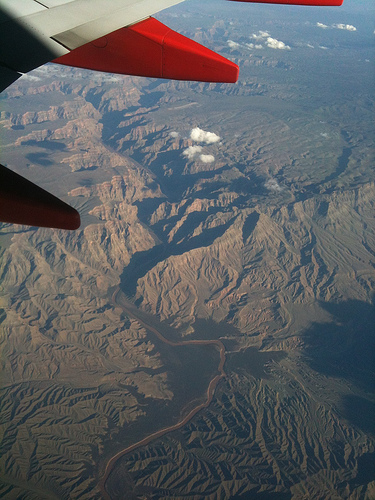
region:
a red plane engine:
[38, 15, 246, 84]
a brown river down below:
[87, 209, 235, 498]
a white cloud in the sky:
[160, 117, 229, 143]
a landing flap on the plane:
[50, 0, 185, 57]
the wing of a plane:
[1, 0, 202, 107]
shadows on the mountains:
[284, 288, 374, 451]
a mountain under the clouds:
[124, 176, 305, 324]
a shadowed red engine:
[0, 148, 101, 231]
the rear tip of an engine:
[225, 58, 245, 98]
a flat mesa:
[0, 86, 139, 260]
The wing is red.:
[33, 11, 246, 101]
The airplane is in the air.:
[1, 0, 276, 226]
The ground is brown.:
[31, 230, 347, 468]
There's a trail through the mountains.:
[73, 275, 239, 496]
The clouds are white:
[150, 108, 229, 172]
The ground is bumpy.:
[34, 107, 354, 270]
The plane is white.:
[1, 0, 211, 66]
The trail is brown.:
[99, 281, 246, 493]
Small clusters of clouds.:
[212, 9, 318, 64]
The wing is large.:
[1, 0, 284, 242]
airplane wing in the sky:
[0, 0, 358, 232]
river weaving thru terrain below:
[67, 88, 240, 497]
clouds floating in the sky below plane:
[167, 124, 224, 164]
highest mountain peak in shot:
[205, 184, 299, 280]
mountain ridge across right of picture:
[140, 168, 373, 292]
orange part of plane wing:
[50, 15, 249, 87]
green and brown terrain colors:
[201, 360, 304, 493]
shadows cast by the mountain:
[114, 110, 213, 301]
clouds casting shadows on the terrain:
[18, 123, 223, 167]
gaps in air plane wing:
[6, 0, 72, 94]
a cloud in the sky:
[196, 150, 220, 168]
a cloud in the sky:
[181, 140, 197, 153]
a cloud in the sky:
[189, 120, 219, 145]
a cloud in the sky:
[165, 131, 181, 140]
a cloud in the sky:
[261, 32, 290, 57]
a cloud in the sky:
[335, 20, 359, 39]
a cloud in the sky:
[229, 35, 245, 51]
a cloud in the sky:
[256, 28, 274, 40]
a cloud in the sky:
[314, 18, 331, 33]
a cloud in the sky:
[311, 41, 331, 54]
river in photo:
[98, 286, 254, 486]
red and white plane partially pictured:
[18, 8, 266, 252]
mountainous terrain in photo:
[46, 106, 283, 499]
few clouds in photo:
[148, 88, 242, 200]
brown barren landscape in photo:
[26, 121, 272, 497]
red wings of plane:
[2, 24, 242, 237]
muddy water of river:
[107, 291, 268, 492]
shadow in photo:
[282, 266, 373, 455]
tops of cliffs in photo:
[11, 98, 138, 299]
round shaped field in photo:
[150, 69, 341, 238]